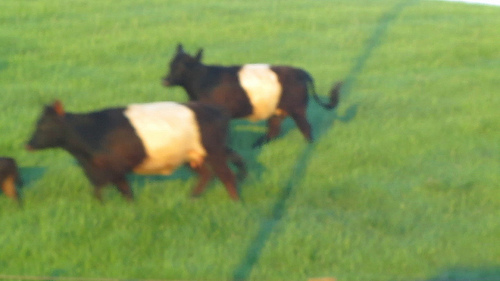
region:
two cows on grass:
[31, 54, 311, 212]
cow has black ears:
[142, 49, 212, 83]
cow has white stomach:
[240, 61, 285, 133]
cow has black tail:
[276, 54, 372, 134]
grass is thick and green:
[369, 134, 496, 252]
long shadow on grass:
[236, 6, 403, 267]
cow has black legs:
[240, 101, 321, 173]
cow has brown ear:
[40, 95, 71, 120]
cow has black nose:
[15, 131, 43, 159]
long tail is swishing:
[311, 78, 358, 125]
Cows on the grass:
[25, 45, 350, 205]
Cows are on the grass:
[20, 42, 343, 206]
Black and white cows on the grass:
[26, 41, 349, 204]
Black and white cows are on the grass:
[18, 36, 344, 211]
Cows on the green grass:
[25, 42, 347, 213]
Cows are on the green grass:
[25, 37, 344, 213]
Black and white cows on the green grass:
[18, 39, 341, 203]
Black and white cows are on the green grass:
[18, 41, 345, 217]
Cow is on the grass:
[21, 95, 255, 212]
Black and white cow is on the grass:
[18, 97, 250, 209]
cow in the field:
[26, 93, 234, 206]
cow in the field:
[168, 42, 360, 141]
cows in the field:
[31, 30, 396, 223]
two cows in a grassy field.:
[22, 40, 347, 209]